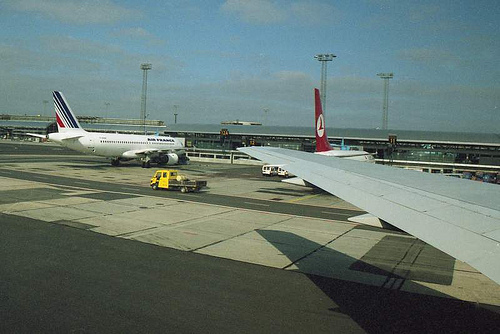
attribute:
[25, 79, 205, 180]
plane — parked, white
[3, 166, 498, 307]
runway — airport's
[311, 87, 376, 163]
airplane — sitting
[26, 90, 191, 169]
airplane — sitting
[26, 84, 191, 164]
jet — white 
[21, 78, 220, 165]
plane — parked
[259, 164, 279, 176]
bus — white 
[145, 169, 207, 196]
towtruck — yellow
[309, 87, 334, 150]
wing — white, red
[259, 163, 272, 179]
car — white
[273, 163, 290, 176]
car — white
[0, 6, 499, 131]
sky — dark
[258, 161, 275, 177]
van — parked, white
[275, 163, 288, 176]
van — parked, white